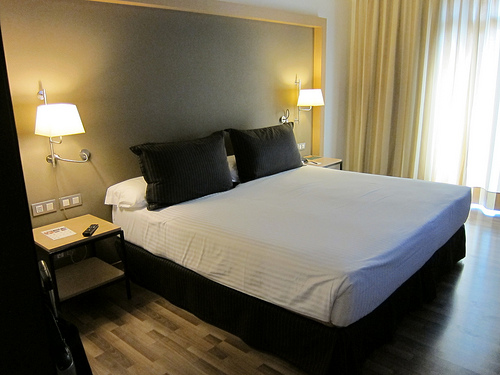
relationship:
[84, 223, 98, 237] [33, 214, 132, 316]
remote on top of table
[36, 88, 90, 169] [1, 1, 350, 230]
lamp hanging on wall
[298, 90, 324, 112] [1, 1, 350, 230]
lamp hanging on wall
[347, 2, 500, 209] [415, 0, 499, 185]
curtain hanging on window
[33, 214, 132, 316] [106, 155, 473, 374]
table next to bed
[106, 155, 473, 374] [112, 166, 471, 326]
bed has bed cover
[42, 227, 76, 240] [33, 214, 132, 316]
paper on top of table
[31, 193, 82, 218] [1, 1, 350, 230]
switch in front of wall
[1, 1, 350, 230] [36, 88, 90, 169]
wall has lamp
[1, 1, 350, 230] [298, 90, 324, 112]
wall has lamp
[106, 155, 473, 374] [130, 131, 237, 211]
bed has pillow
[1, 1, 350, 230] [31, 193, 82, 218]
wall has switch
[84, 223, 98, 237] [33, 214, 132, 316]
remote sitting on table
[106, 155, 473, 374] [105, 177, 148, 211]
bed has pillow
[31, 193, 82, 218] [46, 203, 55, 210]
switch has socket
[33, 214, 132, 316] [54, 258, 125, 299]
table has rack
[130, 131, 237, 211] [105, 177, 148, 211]
pillow in front of pillow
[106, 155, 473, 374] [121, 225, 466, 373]
bed has bed skirt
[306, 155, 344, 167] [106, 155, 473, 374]
table next to bed